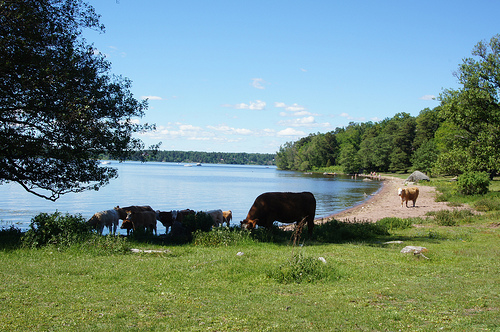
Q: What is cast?
A: Shadow.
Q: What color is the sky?
A: Blue.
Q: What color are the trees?
A: Green.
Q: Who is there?
A: No one.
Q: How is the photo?
A: Clear.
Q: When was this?
A: Daytime.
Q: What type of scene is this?
A: Outdoor.